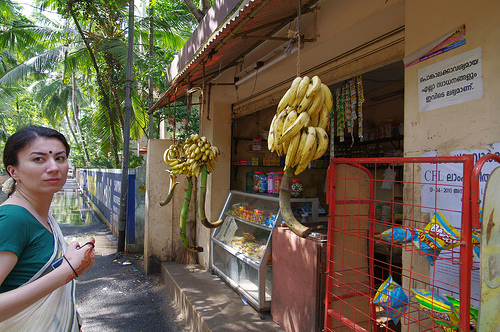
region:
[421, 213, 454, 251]
chips on a rack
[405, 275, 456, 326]
chips on a rack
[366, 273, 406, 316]
chips on a rack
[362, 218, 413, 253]
chips on a rack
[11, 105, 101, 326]
woman wearing a green shirt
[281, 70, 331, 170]
bananas hanging from string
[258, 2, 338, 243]
two bunches of bananas hanging from roof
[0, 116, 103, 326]
woman wearing green and tan outfit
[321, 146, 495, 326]
red grilled metal shelf in front of tan wall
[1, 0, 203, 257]
palm trees next to building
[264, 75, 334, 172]
a yellow bunch of bananas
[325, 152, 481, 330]
red shelf holding food products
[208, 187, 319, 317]
metal counter holding food items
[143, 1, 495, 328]
a business selling food items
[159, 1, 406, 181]
bananas hanging in a store front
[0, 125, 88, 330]
A woman standing on the sidewalk.